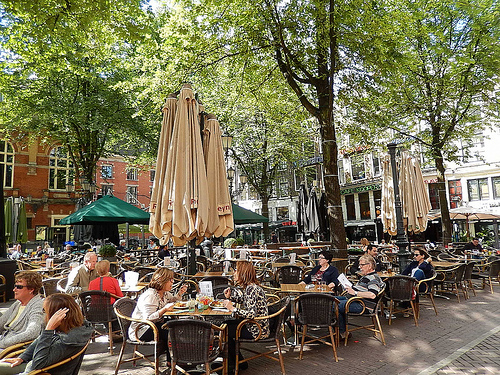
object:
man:
[335, 256, 386, 343]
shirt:
[346, 274, 385, 310]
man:
[399, 246, 433, 294]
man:
[0, 270, 47, 359]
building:
[1, 120, 167, 249]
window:
[2, 137, 14, 190]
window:
[49, 141, 78, 188]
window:
[98, 162, 115, 175]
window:
[102, 183, 114, 193]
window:
[127, 167, 138, 182]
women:
[130, 265, 188, 358]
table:
[430, 259, 463, 271]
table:
[374, 260, 402, 280]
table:
[279, 284, 335, 298]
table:
[280, 243, 312, 255]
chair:
[380, 272, 421, 326]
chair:
[288, 289, 343, 363]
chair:
[158, 319, 232, 373]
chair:
[105, 290, 165, 375]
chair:
[462, 258, 482, 298]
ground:
[435, 313, 498, 355]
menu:
[337, 272, 352, 289]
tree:
[1, 2, 155, 204]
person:
[87, 261, 123, 319]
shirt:
[88, 275, 122, 303]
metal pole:
[385, 143, 414, 309]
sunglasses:
[8, 282, 30, 292]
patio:
[307, 272, 496, 374]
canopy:
[58, 195, 151, 226]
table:
[162, 300, 249, 370]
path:
[440, 327, 482, 352]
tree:
[214, 8, 382, 235]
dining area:
[0, 227, 498, 372]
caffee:
[47, 193, 137, 254]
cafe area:
[0, 215, 497, 374]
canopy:
[143, 82, 235, 247]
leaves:
[83, 52, 159, 127]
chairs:
[342, 273, 394, 346]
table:
[268, 260, 308, 282]